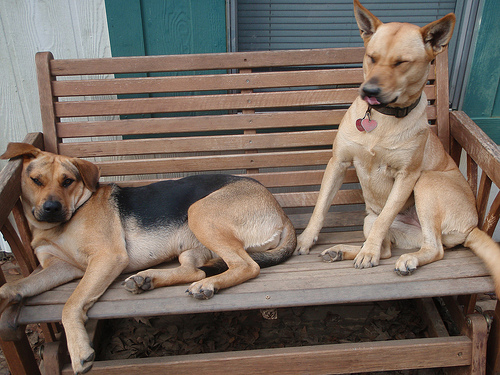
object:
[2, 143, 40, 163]
ear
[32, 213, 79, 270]
arm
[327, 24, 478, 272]
dog sneezing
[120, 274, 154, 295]
pads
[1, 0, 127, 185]
wood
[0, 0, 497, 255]
house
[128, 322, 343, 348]
leaves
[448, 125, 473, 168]
ground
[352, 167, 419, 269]
leg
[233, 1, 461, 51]
gray blinds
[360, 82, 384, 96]
nose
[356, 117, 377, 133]
tag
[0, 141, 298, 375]
dog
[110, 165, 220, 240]
spot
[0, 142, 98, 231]
head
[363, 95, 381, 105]
tongue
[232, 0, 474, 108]
window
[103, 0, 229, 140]
shutter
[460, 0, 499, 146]
shutter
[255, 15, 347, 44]
blinds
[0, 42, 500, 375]
bench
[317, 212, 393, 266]
leg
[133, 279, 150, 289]
feet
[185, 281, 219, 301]
pads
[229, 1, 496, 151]
window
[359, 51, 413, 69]
eyes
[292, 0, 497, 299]
dog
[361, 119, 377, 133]
tag